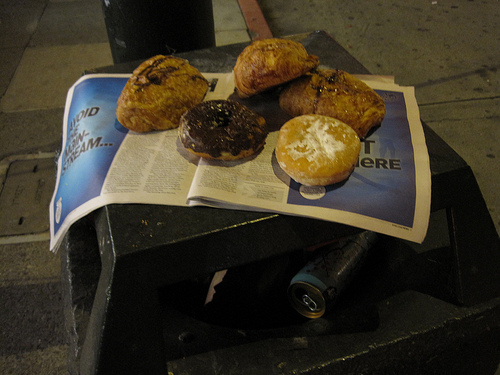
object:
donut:
[229, 33, 321, 103]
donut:
[114, 49, 208, 132]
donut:
[278, 63, 386, 138]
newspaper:
[43, 68, 437, 258]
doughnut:
[272, 110, 363, 191]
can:
[282, 222, 385, 319]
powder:
[291, 117, 347, 167]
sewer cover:
[0, 156, 53, 237]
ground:
[0, 2, 499, 374]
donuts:
[180, 96, 270, 161]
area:
[104, 73, 289, 204]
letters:
[124, 143, 157, 155]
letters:
[160, 156, 188, 168]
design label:
[55, 197, 63, 224]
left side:
[52, 77, 130, 235]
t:
[360, 138, 376, 154]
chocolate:
[180, 100, 268, 158]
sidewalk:
[0, 1, 251, 375]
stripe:
[236, 0, 274, 40]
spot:
[11, 103, 22, 112]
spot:
[47, 62, 56, 71]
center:
[310, 136, 325, 150]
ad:
[286, 85, 416, 228]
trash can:
[40, 29, 499, 374]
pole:
[101, 1, 219, 63]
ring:
[290, 273, 331, 298]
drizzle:
[133, 58, 178, 93]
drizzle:
[311, 69, 351, 98]